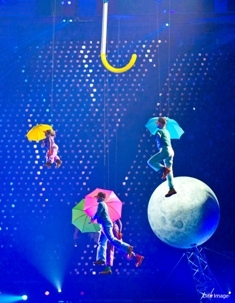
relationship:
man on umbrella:
[147, 116, 176, 197] [145, 114, 185, 139]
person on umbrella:
[90, 193, 133, 264] [83, 186, 121, 223]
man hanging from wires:
[147, 116, 176, 197] [152, 1, 177, 146]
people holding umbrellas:
[8, 114, 178, 268] [24, 6, 188, 230]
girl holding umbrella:
[43, 130, 62, 167] [23, 123, 56, 142]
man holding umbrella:
[147, 116, 176, 197] [148, 113, 180, 137]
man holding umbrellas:
[147, 116, 176, 197] [68, 185, 124, 235]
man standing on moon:
[147, 116, 176, 195] [146, 175, 221, 249]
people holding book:
[44, 129, 62, 171] [48, 149, 52, 154]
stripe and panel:
[21, 22, 217, 280] [55, 69, 129, 154]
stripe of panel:
[21, 22, 217, 280] [55, 69, 129, 154]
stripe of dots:
[21, 22, 217, 280] [10, 38, 211, 278]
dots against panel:
[80, 45, 86, 49] [3, 36, 220, 278]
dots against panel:
[79, 48, 84, 54] [3, 36, 220, 278]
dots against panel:
[83, 53, 88, 58] [3, 36, 220, 278]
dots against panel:
[80, 57, 86, 63] [3, 36, 220, 278]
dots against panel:
[88, 66, 93, 73] [3, 36, 220, 278]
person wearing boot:
[90, 193, 133, 266] [128, 245, 149, 271]